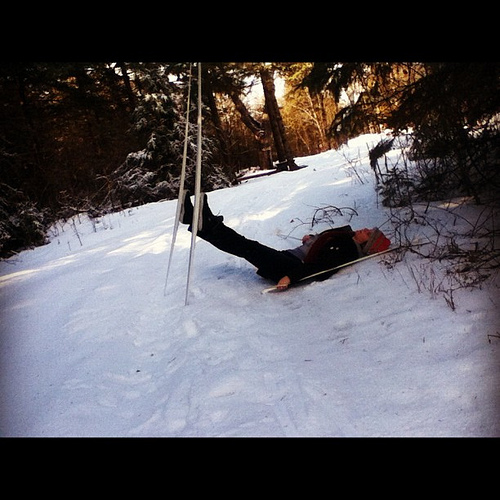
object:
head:
[354, 227, 389, 254]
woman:
[178, 189, 392, 290]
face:
[355, 228, 375, 242]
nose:
[363, 227, 367, 230]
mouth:
[357, 231, 362, 235]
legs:
[208, 227, 243, 258]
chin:
[351, 231, 356, 237]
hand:
[277, 275, 290, 290]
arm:
[293, 247, 341, 284]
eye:
[368, 232, 371, 237]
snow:
[110, 306, 171, 342]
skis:
[163, 60, 202, 303]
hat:
[363, 227, 391, 255]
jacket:
[303, 224, 362, 270]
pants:
[188, 216, 304, 283]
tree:
[27, 59, 105, 222]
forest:
[0, 57, 500, 262]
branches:
[103, 75, 164, 116]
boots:
[180, 191, 223, 231]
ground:
[251, 336, 367, 389]